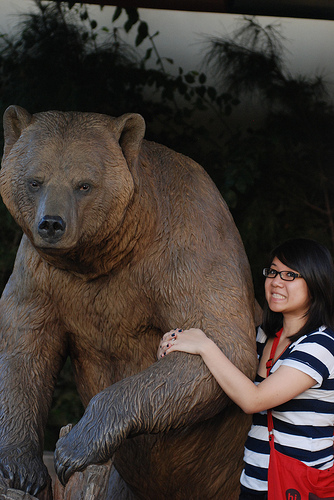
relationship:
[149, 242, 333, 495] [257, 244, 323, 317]
girl has a head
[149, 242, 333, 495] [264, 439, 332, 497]
girl carrying a bag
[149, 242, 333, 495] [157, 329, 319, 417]
girl has a arm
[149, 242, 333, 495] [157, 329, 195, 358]
girl has a hand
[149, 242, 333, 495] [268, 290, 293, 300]
girl has a mouth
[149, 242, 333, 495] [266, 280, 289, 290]
girl has a nose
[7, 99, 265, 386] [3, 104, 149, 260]
bear statue has a head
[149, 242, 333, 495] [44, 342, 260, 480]
girl holding arm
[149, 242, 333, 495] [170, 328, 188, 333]
girl has a nail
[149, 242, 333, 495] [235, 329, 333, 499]
girl wearing a shirt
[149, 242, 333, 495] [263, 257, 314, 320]
girl making a face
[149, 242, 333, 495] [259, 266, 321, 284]
girl wearing glasses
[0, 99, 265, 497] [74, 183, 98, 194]
bear statue has one red eye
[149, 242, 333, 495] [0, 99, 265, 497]
girl posing with a bear statue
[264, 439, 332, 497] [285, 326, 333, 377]
bag over shoulder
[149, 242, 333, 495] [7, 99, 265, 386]
girl holding onto statue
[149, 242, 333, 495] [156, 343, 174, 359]
girl wearing nail polish